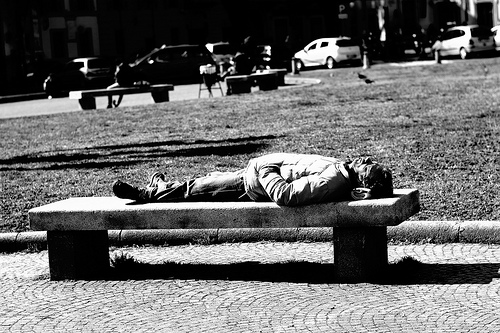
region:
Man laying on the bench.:
[112, 147, 394, 207]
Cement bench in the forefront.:
[26, 181, 423, 281]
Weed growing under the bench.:
[110, 253, 144, 273]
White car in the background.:
[293, 30, 357, 76]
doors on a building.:
[38, 15, 99, 76]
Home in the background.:
[386, 1, 498, 50]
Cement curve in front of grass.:
[3, 217, 497, 247]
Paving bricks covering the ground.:
[1, 241, 498, 331]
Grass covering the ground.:
[1, 67, 496, 229]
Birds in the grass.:
[354, 65, 374, 91]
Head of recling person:
[343, 153, 397, 200]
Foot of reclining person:
[107, 176, 147, 200]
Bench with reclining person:
[21, 147, 422, 283]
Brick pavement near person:
[156, 290, 236, 311]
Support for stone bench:
[44, 229, 118, 286]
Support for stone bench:
[328, 226, 393, 283]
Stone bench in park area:
[66, 79, 175, 113]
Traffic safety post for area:
[358, 49, 372, 72]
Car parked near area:
[287, 36, 364, 68]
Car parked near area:
[427, 23, 498, 61]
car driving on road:
[290, 33, 361, 71]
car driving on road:
[431, 25, 496, 57]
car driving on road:
[205, 42, 235, 65]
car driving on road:
[113, 44, 215, 89]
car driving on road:
[43, 53, 105, 91]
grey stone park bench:
[29, 194, 416, 284]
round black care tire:
[323, 55, 336, 66]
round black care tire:
[295, 59, 305, 69]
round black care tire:
[461, 46, 471, 60]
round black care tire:
[128, 75, 141, 83]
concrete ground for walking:
[63, 272, 410, 323]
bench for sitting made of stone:
[35, 200, 387, 260]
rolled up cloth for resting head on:
[345, 185, 382, 201]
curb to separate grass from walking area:
[415, 215, 496, 240]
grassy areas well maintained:
[380, 80, 482, 147]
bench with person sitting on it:
[70, 65, 171, 100]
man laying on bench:
[115, 157, 380, 202]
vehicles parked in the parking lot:
[298, 37, 485, 64]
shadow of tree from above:
[18, 133, 243, 163]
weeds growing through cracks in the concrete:
[116, 245, 149, 272]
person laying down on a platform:
[99, 141, 399, 208]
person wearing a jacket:
[106, 122, 392, 206]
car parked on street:
[285, 32, 367, 74]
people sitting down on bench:
[220, 35, 290, 95]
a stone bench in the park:
[25, 180, 426, 287]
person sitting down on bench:
[55, 42, 182, 113]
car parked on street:
[421, 23, 498, 63]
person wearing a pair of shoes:
[108, 156, 398, 206]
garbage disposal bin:
[192, 63, 229, 98]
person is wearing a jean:
[106, 148, 406, 204]